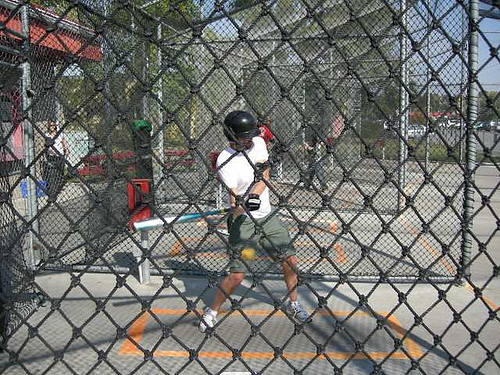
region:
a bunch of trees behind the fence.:
[95, 0, 190, 47]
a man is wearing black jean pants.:
[306, 166, 327, 183]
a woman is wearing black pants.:
[44, 157, 59, 190]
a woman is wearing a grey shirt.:
[46, 136, 63, 151]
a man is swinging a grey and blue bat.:
[129, 203, 231, 238]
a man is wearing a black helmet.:
[216, 107, 267, 143]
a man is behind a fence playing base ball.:
[125, 103, 350, 338]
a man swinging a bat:
[126, 93, 334, 338]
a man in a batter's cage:
[115, 68, 369, 333]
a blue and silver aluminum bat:
[124, 200, 241, 234]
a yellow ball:
[236, 244, 256, 266]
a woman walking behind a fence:
[36, 113, 75, 183]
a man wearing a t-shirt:
[203, 106, 273, 222]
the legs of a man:
[198, 265, 321, 350]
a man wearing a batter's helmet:
[210, 105, 259, 160]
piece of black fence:
[4, 0, 51, 50]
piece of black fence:
[49, 6, 99, 56]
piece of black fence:
[103, 3, 151, 53]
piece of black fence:
[149, 5, 197, 64]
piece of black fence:
[197, 10, 241, 61]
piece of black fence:
[245, 7, 289, 62]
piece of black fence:
[291, 10, 333, 65]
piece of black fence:
[377, 18, 415, 75]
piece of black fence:
[414, 13, 461, 82]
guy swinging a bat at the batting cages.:
[126, 105, 316, 338]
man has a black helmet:
[199, 105, 289, 192]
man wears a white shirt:
[191, 98, 289, 228]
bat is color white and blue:
[122, 205, 242, 230]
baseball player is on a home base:
[116, 102, 430, 373]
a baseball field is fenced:
[9, 3, 499, 368]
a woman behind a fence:
[36, 109, 78, 213]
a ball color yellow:
[234, 243, 264, 264]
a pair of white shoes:
[194, 298, 319, 334]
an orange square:
[116, 298, 426, 369]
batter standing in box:
[186, 101, 318, 335]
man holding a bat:
[135, 108, 326, 337]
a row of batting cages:
[20, 10, 492, 361]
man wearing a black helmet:
[218, 100, 265, 153]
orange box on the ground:
[119, 288, 448, 367]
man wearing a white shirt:
[203, 137, 291, 234]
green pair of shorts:
[229, 212, 303, 277]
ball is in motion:
[232, 240, 257, 269]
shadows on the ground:
[28, 278, 215, 369]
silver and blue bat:
[120, 203, 228, 258]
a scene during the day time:
[23, 55, 468, 371]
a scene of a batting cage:
[33, 11, 495, 370]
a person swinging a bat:
[121, 100, 321, 352]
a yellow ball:
[228, 239, 263, 270]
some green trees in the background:
[81, 8, 396, 165]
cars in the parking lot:
[369, 98, 496, 164]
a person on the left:
[28, 115, 83, 212]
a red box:
[116, 167, 155, 257]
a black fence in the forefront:
[11, 58, 493, 345]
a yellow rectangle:
[109, 276, 446, 373]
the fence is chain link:
[386, 174, 449, 239]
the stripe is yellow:
[393, 340, 418, 349]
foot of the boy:
[197, 313, 228, 328]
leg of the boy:
[210, 276, 238, 298]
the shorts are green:
[270, 223, 297, 235]